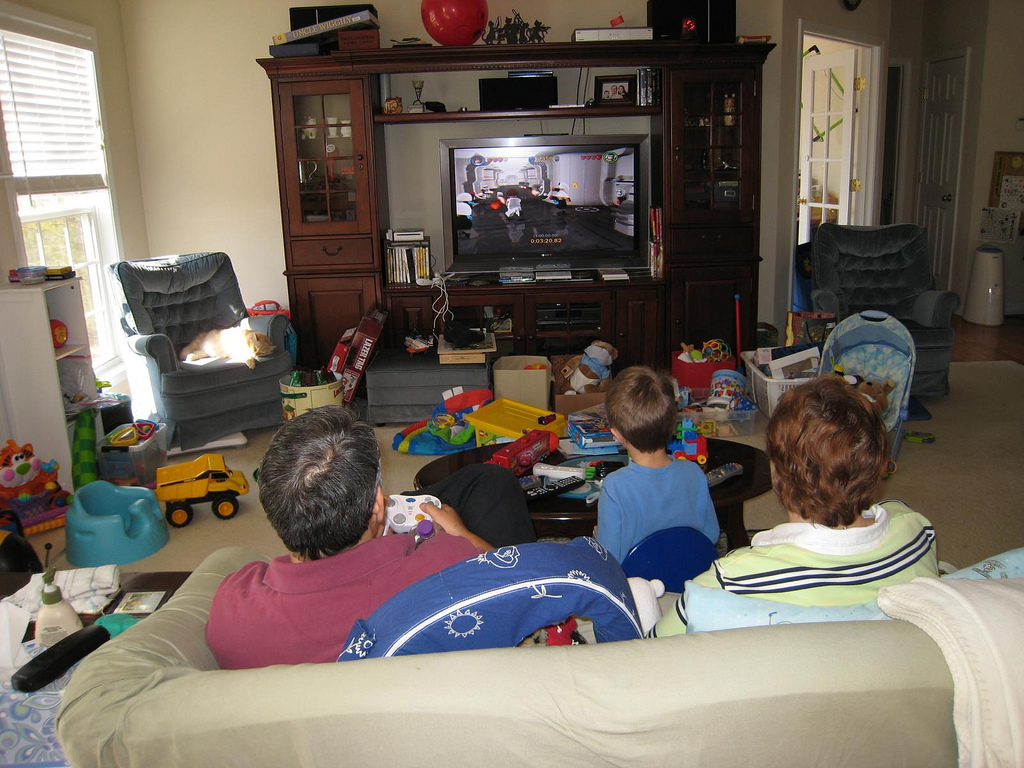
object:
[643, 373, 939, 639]
person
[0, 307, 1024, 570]
floor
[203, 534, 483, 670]
red shirt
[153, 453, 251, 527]
dump truck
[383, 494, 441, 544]
game controller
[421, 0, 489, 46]
red ball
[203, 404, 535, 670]
man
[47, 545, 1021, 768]
couch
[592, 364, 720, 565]
boy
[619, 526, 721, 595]
chair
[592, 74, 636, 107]
picture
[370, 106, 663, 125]
shelf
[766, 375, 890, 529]
short hair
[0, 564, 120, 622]
towel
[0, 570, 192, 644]
table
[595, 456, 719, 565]
shirt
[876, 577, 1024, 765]
blanket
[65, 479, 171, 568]
chair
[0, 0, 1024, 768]
room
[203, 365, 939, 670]
people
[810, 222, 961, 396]
chair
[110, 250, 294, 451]
chair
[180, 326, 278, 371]
cat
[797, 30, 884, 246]
window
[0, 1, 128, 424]
window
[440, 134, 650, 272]
entertainment center